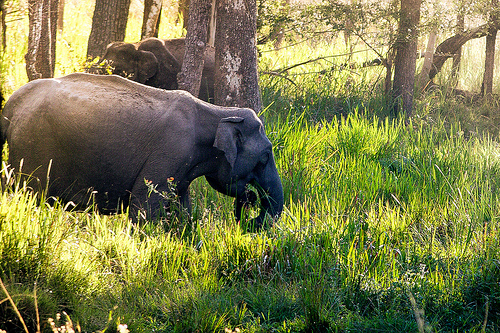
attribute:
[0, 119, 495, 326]
grass — tall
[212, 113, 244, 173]
ears — floppy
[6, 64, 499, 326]
grass — tall, growing